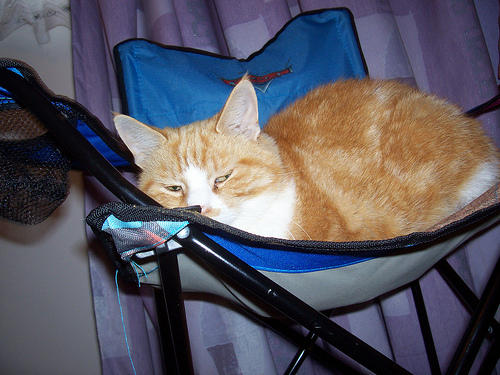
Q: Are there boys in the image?
A: No, there are no boys.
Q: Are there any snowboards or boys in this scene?
A: No, there are no boys or snowboards.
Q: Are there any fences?
A: No, there are no fences.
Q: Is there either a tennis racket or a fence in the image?
A: No, there are no fences or rackets.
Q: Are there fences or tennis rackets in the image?
A: No, there are no fences or tennis rackets.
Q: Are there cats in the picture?
A: Yes, there is a cat.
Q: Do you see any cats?
A: Yes, there is a cat.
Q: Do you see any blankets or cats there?
A: Yes, there is a cat.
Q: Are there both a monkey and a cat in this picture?
A: No, there is a cat but no monkeys.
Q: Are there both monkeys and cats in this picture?
A: No, there is a cat but no monkeys.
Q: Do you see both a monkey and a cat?
A: No, there is a cat but no monkeys.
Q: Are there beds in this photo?
A: No, there are no beds.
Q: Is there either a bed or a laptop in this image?
A: No, there are no beds or laptops.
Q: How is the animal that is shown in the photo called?
A: The animal is a cat.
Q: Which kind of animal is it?
A: The animal is a cat.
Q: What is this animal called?
A: This is a cat.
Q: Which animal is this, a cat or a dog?
A: This is a cat.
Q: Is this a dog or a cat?
A: This is a cat.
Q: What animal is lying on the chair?
A: The cat is lying on the chair.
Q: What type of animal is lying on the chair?
A: The animal is a cat.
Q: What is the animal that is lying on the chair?
A: The animal is a cat.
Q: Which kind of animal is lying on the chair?
A: The animal is a cat.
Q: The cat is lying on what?
A: The cat is lying on the chair.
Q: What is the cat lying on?
A: The cat is lying on the chair.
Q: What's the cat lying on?
A: The cat is lying on the chair.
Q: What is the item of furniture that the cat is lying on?
A: The piece of furniture is a chair.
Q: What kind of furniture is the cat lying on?
A: The cat is lying on the chair.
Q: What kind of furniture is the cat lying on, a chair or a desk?
A: The cat is lying on a chair.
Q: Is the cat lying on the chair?
A: Yes, the cat is lying on the chair.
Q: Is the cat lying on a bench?
A: No, the cat is lying on the chair.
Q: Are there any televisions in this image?
A: No, there are no televisions.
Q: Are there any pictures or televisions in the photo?
A: No, there are no televisions or pictures.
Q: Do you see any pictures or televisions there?
A: No, there are no televisions or pictures.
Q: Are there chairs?
A: Yes, there is a chair.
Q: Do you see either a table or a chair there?
A: Yes, there is a chair.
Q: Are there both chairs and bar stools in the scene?
A: No, there is a chair but no bar stools.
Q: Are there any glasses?
A: No, there are no glasses.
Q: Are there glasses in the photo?
A: No, there are no glasses.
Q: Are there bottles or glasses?
A: No, there are no glasses or bottles.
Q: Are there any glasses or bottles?
A: No, there are no glasses or bottles.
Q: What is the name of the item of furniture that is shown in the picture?
A: The piece of furniture is a chair.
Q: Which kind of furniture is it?
A: The piece of furniture is a chair.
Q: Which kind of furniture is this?
A: This is a chair.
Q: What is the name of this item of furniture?
A: This is a chair.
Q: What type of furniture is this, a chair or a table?
A: This is a chair.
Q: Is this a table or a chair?
A: This is a chair.